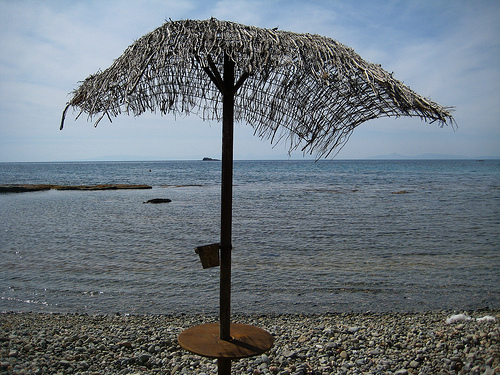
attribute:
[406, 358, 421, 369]
rock — small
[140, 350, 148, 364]
rock — small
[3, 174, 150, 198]
land protusion — small 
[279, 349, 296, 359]
rock — large, grey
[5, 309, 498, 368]
beach — rocky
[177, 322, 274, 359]
table — brown 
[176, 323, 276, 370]
table — small, round, brown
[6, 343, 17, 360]
rock — small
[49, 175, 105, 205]
peninsula — narrow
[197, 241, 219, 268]
bucket — Small 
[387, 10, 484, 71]
sky — cloudy, blue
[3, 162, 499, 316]
water — large 